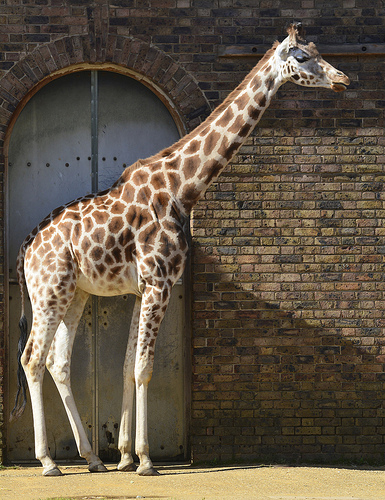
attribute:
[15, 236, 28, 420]
tail — black 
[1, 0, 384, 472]
brick wall — red, brown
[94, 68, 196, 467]
door — metal, arched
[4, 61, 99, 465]
door — metal, arched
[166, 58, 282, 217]
spotted neck — long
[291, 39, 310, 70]
eyes — closed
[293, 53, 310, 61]
eye — brown 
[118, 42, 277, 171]
giraffe mane — brown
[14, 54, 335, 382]
spots — brown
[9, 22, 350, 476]
giraffe — brown, white, big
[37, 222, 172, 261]
spots — brown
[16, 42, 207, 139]
archway — brick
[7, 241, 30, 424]
tail — long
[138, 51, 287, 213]
neck — long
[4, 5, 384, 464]
wall — brick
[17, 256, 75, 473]
leg — long 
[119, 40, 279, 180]
mane — short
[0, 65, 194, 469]
door — rusted, metal, steel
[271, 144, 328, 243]
wall — brick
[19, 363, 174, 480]
legs — white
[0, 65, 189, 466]
gate — big, strong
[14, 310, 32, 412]
hair — black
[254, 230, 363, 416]
brick — brown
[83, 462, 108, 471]
hoof — tan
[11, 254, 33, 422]
tail — black